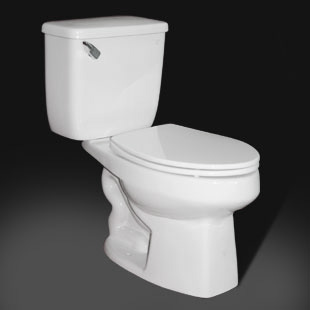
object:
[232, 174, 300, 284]
shadow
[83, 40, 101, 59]
handle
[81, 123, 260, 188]
bottom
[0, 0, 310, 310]
toilet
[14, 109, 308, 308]
floor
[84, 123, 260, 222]
bowl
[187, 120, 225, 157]
light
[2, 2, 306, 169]
black background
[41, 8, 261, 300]
white toilet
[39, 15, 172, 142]
back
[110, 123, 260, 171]
lid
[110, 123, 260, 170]
protective pad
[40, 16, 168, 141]
tank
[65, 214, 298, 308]
ground